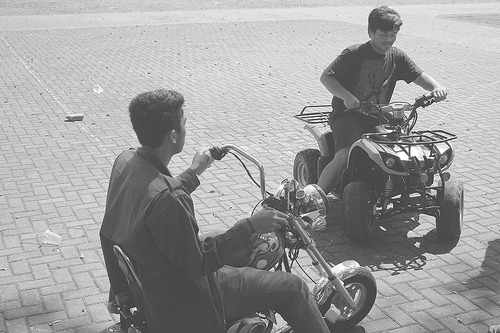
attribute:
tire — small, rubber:
[291, 146, 321, 186]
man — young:
[291, 4, 453, 245]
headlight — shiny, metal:
[293, 180, 332, 235]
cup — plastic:
[32, 221, 74, 261]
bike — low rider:
[186, 175, 381, 328]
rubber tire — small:
[335, 179, 372, 249]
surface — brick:
[2, 22, 498, 331]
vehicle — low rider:
[308, 137, 418, 242]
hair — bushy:
[365, 4, 402, 31]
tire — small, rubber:
[301, 263, 390, 324]